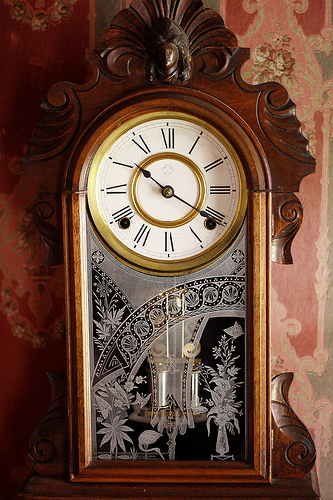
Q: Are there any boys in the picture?
A: No, there are no boys.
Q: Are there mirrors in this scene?
A: No, there are no mirrors.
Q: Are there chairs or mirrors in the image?
A: No, there are no mirrors or chairs.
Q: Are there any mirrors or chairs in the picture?
A: No, there are no mirrors or chairs.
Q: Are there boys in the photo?
A: No, there are no boys.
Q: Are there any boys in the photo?
A: No, there are no boys.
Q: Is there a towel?
A: No, there are no towels.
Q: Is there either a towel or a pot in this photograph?
A: No, there are no towels or pots.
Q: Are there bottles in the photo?
A: No, there are no bottles.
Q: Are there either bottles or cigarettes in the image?
A: No, there are no bottles or cigarettes.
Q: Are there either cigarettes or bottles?
A: No, there are no bottles or cigarettes.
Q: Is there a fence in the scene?
A: No, there are no fences.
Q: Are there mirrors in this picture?
A: No, there are no mirrors.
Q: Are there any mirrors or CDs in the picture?
A: No, there are no mirrors or cds.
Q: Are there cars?
A: No, there are no cars.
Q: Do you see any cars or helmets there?
A: No, there are no cars or helmets.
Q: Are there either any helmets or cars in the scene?
A: No, there are no cars or helmets.